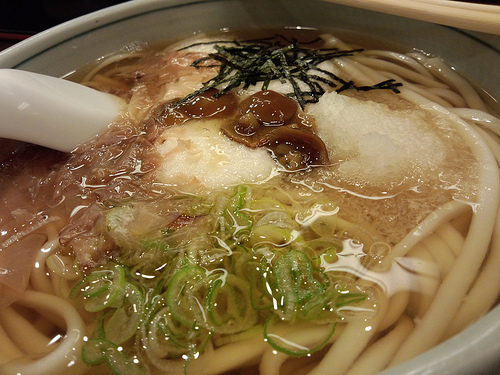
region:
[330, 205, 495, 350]
There are noodles in the soup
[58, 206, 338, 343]
There are green vegetables in the soup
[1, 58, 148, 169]
The handle of the spoon is white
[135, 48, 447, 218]
There is a white substance in the soup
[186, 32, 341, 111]
There is a dried substance on top the white stuff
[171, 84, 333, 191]
There is a brown substance on top the white stuff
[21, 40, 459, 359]
food in a bowl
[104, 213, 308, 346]
green food in bowl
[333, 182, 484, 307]
noodles in the bowl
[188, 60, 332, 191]
brown gravy in bowl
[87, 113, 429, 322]
many pieces of food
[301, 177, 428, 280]
liquid in the bowl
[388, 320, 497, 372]
side of the bowl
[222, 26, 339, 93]
thin pieces of food in bowl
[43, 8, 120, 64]
side of the bowl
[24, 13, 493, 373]
a bowl of food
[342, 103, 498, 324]
noodles in the bowl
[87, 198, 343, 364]
scallions in the bowl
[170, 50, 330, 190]
brown item in bowl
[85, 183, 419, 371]
broth in the bowl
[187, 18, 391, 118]
green shreds in the bowl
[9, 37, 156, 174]
a white eating utensil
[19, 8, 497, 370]
the bowl is white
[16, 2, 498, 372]
green trim on bowl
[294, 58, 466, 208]
white substance in bowl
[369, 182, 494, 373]
onions on the edge of the bowl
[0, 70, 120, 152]
the handle of the spoon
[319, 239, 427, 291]
light reflecting off the surface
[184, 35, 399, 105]
food that looks like black string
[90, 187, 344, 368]
a collection of green food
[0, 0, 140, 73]
the outer edge of the bowl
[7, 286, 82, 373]
a semi circle of an onion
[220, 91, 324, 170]
a brown piece of food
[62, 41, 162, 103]
brown liquid in the soup bowl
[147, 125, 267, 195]
something that looks like a dumpling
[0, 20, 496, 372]
Asian style hot soup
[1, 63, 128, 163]
Handle of spoon in soup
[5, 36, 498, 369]
Noodles in soup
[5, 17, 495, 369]
Clear broth of soup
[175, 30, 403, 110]
Green spices in soup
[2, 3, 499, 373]
White porcelain bowl for soup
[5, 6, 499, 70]
blue trim on bowl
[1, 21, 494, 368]
Light reflection spots in soup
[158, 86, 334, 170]
Mushrooms in soup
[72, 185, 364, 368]
green onions in soup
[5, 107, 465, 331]
Food in the plate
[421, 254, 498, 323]
Pasta in the bowl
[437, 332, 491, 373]
A gray bowl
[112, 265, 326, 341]
Green vegetables on the bowl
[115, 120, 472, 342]
Food in the bowl.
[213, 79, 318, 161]
Brown mushroom in the liquid.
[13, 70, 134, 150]
Handle of a spoon in the liquid food.